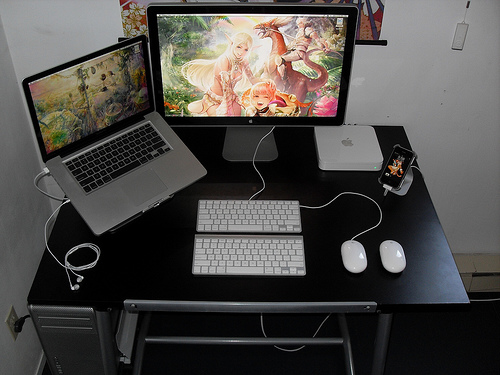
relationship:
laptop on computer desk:
[23, 34, 207, 233] [28, 113, 469, 366]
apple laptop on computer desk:
[23, 34, 207, 233] [28, 113, 469, 366]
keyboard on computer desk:
[196, 198, 305, 232] [28, 113, 469, 366]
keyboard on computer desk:
[195, 237, 305, 273] [28, 113, 469, 366]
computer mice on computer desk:
[340, 239, 369, 274] [28, 113, 469, 366]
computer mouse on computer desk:
[381, 241, 404, 272] [28, 113, 469, 366]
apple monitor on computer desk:
[146, 10, 352, 122] [28, 113, 469, 366]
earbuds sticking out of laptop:
[44, 197, 101, 291] [23, 34, 207, 233]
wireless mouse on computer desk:
[381, 241, 404, 272] [28, 113, 469, 366]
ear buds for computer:
[60, 240, 106, 290] [23, 34, 207, 233]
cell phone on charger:
[381, 142, 411, 187] [387, 156, 416, 192]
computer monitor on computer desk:
[146, 10, 352, 122] [28, 113, 469, 366]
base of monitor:
[221, 128, 284, 163] [146, 10, 352, 122]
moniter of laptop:
[31, 49, 165, 145] [23, 34, 207, 233]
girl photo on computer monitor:
[201, 34, 259, 113] [146, 10, 352, 122]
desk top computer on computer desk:
[146, 10, 352, 122] [28, 113, 469, 366]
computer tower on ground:
[34, 306, 117, 370] [31, 318, 500, 366]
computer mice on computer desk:
[340, 239, 408, 273] [28, 113, 469, 366]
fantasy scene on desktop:
[181, 34, 337, 114] [146, 10, 352, 122]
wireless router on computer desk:
[316, 127, 385, 168] [28, 113, 469, 366]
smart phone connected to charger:
[381, 142, 411, 187] [387, 156, 416, 192]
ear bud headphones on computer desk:
[60, 240, 106, 290] [28, 113, 469, 366]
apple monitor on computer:
[181, 34, 337, 114] [146, 10, 352, 122]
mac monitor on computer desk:
[146, 10, 352, 122] [28, 113, 469, 366]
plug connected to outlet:
[14, 318, 30, 331] [7, 307, 26, 339]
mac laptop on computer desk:
[23, 34, 207, 233] [28, 113, 469, 366]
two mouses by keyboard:
[340, 239, 408, 273] [196, 198, 305, 232]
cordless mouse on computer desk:
[381, 241, 404, 272] [28, 113, 469, 366]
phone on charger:
[381, 142, 411, 187] [387, 156, 416, 192]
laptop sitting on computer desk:
[23, 34, 207, 233] [28, 113, 469, 366]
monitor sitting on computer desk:
[146, 10, 352, 122] [28, 113, 469, 366]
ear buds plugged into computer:
[60, 240, 106, 290] [23, 34, 207, 233]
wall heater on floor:
[449, 254, 499, 292] [394, 300, 499, 371]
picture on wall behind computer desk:
[122, 4, 386, 42] [28, 113, 469, 366]